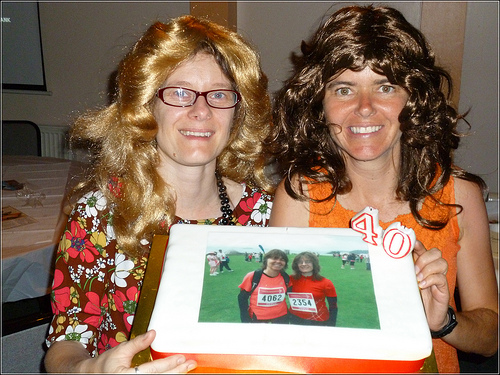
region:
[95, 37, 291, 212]
a woman wearing glasses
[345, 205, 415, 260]
candles on the cake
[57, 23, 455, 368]
women holding a cake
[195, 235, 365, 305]
a picture on the cake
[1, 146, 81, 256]
a table behind the women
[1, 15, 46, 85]
a screen on the wall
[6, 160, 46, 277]
a white table cloth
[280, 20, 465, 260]
a girl wearing an orange shirt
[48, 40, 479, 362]
two women smiling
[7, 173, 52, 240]
items on the table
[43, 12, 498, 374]
two women holding cake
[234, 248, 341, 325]
two women with red shirts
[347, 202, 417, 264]
number 40 on cake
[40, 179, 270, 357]
flowered shirt on woman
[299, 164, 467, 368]
orange shirt on woman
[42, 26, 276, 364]
woman has on glasses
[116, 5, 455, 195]
two women smiling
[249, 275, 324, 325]
numbers on women's chests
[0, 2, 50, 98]
board on wall in background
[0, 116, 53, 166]
gray chair behind table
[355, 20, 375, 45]
woman with brown hair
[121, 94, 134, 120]
woman with blonde hair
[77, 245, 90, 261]
red color in shirt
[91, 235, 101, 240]
beige color in shirt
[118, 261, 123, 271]
white color in shirt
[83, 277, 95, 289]
green color in shirt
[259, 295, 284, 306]
number on orange shirt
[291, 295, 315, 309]
number on red shirt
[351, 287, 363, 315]
green grass in field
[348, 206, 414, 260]
number forty on cake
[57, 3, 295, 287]
woman wears a wig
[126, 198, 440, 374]
number 40 on corner of cake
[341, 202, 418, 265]
number 40 is white and red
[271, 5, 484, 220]
woman is happy smiling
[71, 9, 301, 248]
woman is happy smiling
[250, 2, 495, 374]
woman has an orange dress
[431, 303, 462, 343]
black clock on wrist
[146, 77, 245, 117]
glasses on face of woman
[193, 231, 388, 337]
two woman in a picture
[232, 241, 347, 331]
women wears red tops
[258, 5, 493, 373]
woman on right holding cake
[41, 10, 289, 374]
woman on left holding cake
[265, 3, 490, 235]
woman wearing brown wig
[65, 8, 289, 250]
woman wearing blonde wig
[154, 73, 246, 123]
woman wearing glasses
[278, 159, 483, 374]
woman wearing orange dress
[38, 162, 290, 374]
woman wearing flower dress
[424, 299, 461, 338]
woman wearing a watch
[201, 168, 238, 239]
woman wearing necklace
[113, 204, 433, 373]
cake with a picture on it